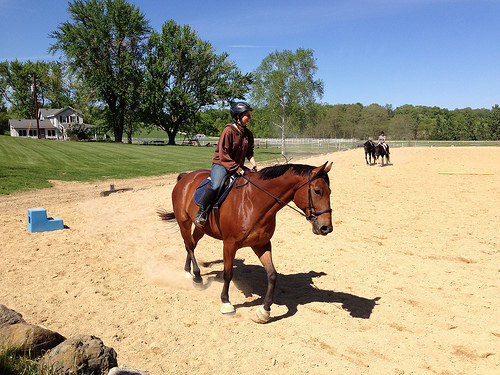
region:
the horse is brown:
[146, 136, 389, 344]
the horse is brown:
[230, 102, 335, 370]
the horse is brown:
[232, 170, 337, 295]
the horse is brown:
[147, 97, 298, 317]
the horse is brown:
[90, 20, 335, 370]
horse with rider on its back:
[129, 77, 363, 312]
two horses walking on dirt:
[354, 119, 409, 169]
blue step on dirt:
[17, 201, 92, 241]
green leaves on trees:
[73, 9, 228, 139]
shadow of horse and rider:
[184, 237, 408, 353]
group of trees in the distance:
[307, 88, 497, 158]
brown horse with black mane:
[236, 156, 373, 295]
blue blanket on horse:
[158, 143, 298, 256]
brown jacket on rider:
[216, 83, 285, 198]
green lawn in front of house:
[9, 70, 119, 172]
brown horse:
[251, 170, 326, 215]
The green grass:
[45, 130, 117, 165]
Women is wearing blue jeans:
[210, 160, 226, 200]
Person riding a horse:
[372, 126, 393, 147]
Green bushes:
[433, 107, 491, 133]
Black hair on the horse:
[257, 162, 305, 177]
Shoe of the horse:
[250, 298, 268, 328]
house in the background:
[10, 98, 88, 138]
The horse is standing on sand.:
[235, 330, 370, 370]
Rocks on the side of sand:
[16, 327, 88, 370]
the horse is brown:
[204, 138, 241, 190]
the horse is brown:
[196, 137, 266, 368]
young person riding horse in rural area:
[98, 72, 431, 319]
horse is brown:
[152, 160, 318, 312]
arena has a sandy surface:
[161, 261, 441, 343]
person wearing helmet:
[218, 95, 260, 139]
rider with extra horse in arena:
[354, 124, 405, 169]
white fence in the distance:
[258, 131, 355, 157]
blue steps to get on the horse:
[25, 193, 83, 248]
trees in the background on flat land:
[222, 80, 482, 135]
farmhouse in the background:
[0, 88, 111, 154]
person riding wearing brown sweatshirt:
[204, 124, 258, 190]